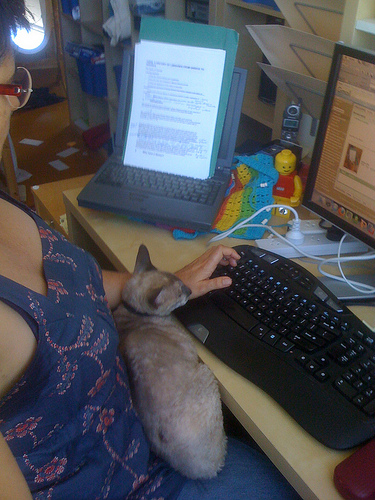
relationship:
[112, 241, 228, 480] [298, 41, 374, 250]
cat in front of monitor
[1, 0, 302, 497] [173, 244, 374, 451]
woman typing on keyboard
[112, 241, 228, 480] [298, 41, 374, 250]
cat looking at monitor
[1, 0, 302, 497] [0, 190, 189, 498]
woman wearing shirt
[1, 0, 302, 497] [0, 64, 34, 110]
woman wearing glasses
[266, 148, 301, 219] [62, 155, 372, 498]
lego toy on top of desk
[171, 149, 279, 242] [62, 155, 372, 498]
crochet on top of desk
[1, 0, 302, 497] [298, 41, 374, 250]
woman looking at monitor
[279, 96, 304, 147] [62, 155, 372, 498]
cordless phone on top of desk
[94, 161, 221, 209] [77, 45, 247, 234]
keyboard of laptop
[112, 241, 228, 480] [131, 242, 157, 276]
cat has ear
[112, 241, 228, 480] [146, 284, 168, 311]
cat has ear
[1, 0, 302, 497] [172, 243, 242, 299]
woman has hand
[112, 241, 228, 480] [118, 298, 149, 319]
cat wearing collar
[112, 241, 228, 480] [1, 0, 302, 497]
cat laying on woman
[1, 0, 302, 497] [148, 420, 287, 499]
woman has lap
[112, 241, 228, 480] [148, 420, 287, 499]
cat laying on lap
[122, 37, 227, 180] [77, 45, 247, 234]
papers leaning on laptop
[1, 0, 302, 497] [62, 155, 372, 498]
woman sitting in front of desk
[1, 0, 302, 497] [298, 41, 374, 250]
woman sitting in front of monitor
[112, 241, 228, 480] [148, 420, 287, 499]
cat sitting on lap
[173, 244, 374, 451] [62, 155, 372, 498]
keyboard on top of desk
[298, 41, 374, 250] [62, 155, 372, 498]
monitor on top of desk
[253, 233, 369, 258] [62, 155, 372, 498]
power strip on top of desk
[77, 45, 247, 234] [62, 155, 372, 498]
laptop on top of desk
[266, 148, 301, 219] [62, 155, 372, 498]
lego toy sitting o top of desk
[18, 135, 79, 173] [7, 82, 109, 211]
evelopes spread o floor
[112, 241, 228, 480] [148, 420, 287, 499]
cat sitting o lap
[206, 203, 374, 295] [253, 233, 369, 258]
power cord plugged into power strip